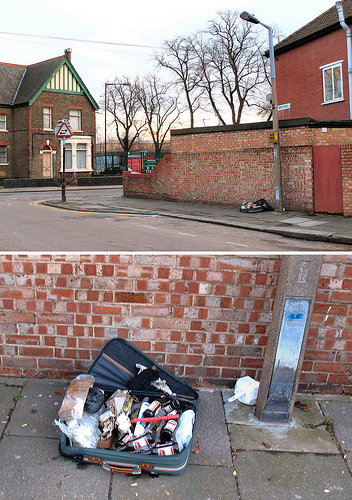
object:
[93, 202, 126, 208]
leaves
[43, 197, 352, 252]
sidewalk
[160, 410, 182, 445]
beer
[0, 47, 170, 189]
houses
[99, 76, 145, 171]
tree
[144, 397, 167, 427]
beer bottle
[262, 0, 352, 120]
house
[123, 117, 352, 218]
wall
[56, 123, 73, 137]
door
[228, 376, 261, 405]
bag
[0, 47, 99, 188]
house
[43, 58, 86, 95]
trim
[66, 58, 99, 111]
roof green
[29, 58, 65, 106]
roof green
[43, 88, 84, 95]
roof green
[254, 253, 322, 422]
lamp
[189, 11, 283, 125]
tree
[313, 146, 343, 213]
gate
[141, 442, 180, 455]
beer bottle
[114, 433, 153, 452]
beer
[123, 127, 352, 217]
brick wall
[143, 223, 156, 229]
line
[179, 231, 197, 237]
line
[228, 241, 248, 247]
line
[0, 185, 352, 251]
ground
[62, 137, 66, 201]
pole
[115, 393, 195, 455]
bottles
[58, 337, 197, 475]
luggage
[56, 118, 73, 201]
street sign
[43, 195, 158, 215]
corner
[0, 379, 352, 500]
ground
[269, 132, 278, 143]
sign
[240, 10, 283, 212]
post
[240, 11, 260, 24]
lamp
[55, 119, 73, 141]
sign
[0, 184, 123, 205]
street